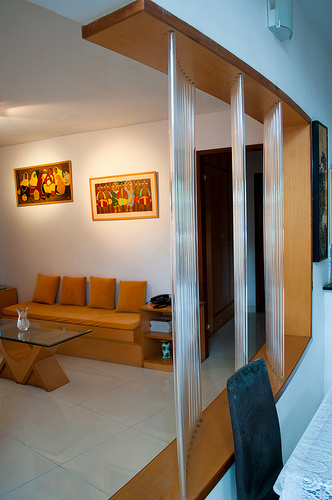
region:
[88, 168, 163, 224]
a picture with white matting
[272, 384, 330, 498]
a lace table cloth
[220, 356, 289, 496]
a chair at a table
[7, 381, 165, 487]
a white tile floor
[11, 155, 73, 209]
a framed picture on the wall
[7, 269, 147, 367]
a couch against a wall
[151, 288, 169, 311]
a black phone on a table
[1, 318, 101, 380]
a glass coffee table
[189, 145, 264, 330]
a wood frame doorway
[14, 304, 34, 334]
a vase on a coffee table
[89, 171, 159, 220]
a framed artwork attached to the wall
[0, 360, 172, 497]
tiled living room floor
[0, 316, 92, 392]
a wood and glass coffee table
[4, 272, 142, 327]
an orange sofa with four pillows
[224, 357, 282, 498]
a black dinning chair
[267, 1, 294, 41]
an electronic fire alarm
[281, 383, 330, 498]
the dinning table and tablecloth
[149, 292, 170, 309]
a telephone land line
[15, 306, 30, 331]
a crystal vase on top of the coffee table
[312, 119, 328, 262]
a picture frame mounted on the dinning room wall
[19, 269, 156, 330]
yellow couch with cushions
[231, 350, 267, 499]
blue velvet back of chair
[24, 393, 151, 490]
white tile flooring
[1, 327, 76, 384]
glass coffee table with brown legs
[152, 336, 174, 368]
candle under side table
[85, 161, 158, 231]
picture on a wall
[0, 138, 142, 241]
two pictures on wall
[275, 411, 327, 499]
small lace table cloth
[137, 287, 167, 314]
black phone on side table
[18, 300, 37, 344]
vase on glass table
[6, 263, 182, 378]
the couch is orange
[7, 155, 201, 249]
2 pictures are framed above couch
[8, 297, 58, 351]
a glass vase is on table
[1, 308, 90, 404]
the table is made of glass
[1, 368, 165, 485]
the floor is tiled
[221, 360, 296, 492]
the chair is black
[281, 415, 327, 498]
the tablecloth is white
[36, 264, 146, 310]
4 pillows are pictured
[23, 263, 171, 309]
the pillows are orange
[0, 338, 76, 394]
the base of table is made of wood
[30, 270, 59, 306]
an orange pillow cushion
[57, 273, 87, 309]
an orange pillow cushion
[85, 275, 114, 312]
an orange pillow cushion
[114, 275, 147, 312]
an orange pillow cushion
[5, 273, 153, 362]
an orange couch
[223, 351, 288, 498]
a dark blue chair back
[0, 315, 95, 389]
a wooden and glass coffee table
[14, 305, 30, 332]
a crystal glass vase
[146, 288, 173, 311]
a black telephone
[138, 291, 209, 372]
a wooden end table